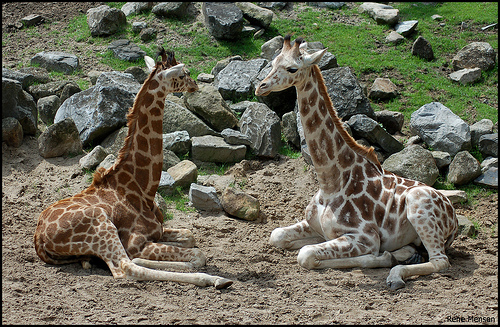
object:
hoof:
[214, 276, 233, 291]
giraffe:
[35, 47, 233, 290]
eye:
[288, 67, 299, 73]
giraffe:
[255, 37, 459, 290]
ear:
[163, 63, 183, 78]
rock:
[167, 158, 197, 189]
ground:
[3, 235, 500, 325]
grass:
[311, 14, 363, 46]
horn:
[293, 37, 303, 52]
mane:
[312, 64, 366, 155]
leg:
[107, 235, 233, 288]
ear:
[302, 47, 328, 65]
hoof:
[388, 280, 407, 291]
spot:
[136, 133, 149, 151]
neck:
[110, 90, 166, 203]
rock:
[59, 73, 143, 138]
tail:
[34, 251, 92, 271]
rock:
[409, 35, 434, 59]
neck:
[298, 66, 384, 192]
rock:
[222, 187, 260, 221]